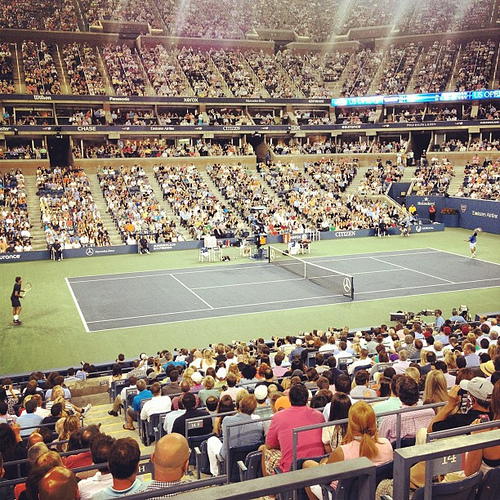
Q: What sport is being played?
A: Tennis.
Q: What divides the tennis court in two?
A: The net.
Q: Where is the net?
A: In the middle of the court.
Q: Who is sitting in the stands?
A: The spectators.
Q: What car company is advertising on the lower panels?
A: Mercedes.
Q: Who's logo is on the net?
A: Mercedes.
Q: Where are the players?
A: On the court.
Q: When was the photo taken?
A: Daytime.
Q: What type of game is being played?
A: Tennis.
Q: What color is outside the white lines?
A: Green.